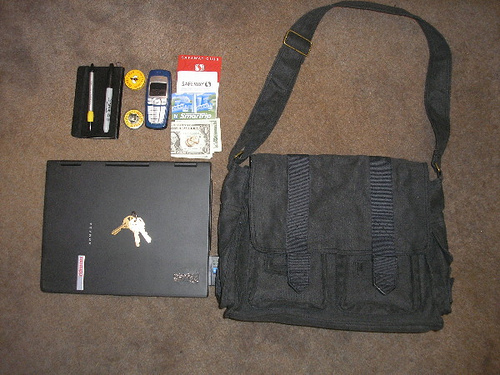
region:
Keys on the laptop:
[107, 209, 155, 249]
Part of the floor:
[125, 324, 193, 347]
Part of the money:
[173, 129, 181, 144]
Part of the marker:
[105, 99, 110, 120]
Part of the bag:
[317, 188, 369, 220]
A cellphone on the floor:
[143, 64, 173, 131]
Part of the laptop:
[51, 172, 78, 197]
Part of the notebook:
[75, 109, 80, 123]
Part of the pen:
[88, 78, 92, 99]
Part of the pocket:
[265, 281, 283, 298]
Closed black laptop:
[39, 157, 211, 299]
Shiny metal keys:
[110, 207, 151, 250]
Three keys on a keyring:
[108, 206, 153, 249]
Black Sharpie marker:
[101, 60, 118, 135]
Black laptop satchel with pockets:
[212, 1, 457, 334]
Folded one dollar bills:
[165, 115, 222, 160]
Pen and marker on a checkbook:
[70, 60, 125, 140]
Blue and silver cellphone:
[141, 66, 171, 131]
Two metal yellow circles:
[121, 65, 142, 130]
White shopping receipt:
[174, 69, 219, 97]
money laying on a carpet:
[161, 119, 222, 157]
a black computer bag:
[221, 1, 488, 326]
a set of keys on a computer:
[109, 207, 163, 247]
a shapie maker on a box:
[101, 60, 120, 132]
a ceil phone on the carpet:
[146, 67, 171, 131]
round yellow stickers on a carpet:
[123, 106, 146, 131]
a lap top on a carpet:
[39, 150, 211, 305]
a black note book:
[75, 65, 128, 140]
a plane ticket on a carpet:
[178, 47, 224, 112]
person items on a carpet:
[5, 5, 489, 367]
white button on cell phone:
[158, 118, 164, 125]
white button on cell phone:
[153, 115, 158, 121]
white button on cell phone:
[148, 118, 155, 123]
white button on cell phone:
[158, 110, 168, 115]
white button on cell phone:
[153, 110, 160, 117]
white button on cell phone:
[147, 111, 154, 117]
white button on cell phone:
[160, 104, 165, 112]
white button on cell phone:
[153, 104, 160, 112]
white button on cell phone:
[147, 105, 154, 110]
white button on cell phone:
[159, 95, 167, 105]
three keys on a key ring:
[106, 211, 152, 249]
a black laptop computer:
[37, 156, 226, 307]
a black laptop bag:
[220, 141, 443, 336]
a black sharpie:
[100, 58, 115, 135]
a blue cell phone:
[142, 63, 169, 127]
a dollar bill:
[170, 121, 222, 160]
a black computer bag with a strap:
[224, 15, 457, 327]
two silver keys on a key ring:
[130, 197, 150, 253]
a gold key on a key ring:
[112, 210, 133, 241]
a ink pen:
[78, 55, 96, 130]